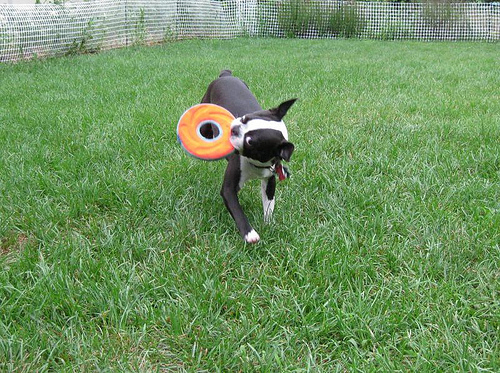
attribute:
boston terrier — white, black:
[194, 67, 301, 242]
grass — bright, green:
[2, 32, 497, 371]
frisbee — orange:
[160, 86, 272, 197]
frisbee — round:
[147, 87, 246, 157]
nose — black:
[225, 122, 247, 142]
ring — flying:
[154, 83, 234, 168]